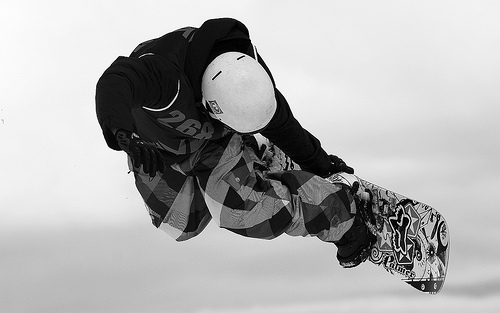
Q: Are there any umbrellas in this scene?
A: No, there are no umbrellas.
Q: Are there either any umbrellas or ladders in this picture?
A: No, there are no umbrellas or ladders.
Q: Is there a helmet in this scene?
A: Yes, there is a helmet.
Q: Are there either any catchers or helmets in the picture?
A: Yes, there is a helmet.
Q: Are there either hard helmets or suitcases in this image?
A: Yes, there is a hard helmet.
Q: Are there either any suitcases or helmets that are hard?
A: Yes, the helmet is hard.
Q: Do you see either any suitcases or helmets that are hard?
A: Yes, the helmet is hard.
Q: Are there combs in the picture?
A: No, there are no combs.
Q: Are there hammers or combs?
A: No, there are no combs or hammers.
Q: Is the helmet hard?
A: Yes, the helmet is hard.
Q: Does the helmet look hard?
A: Yes, the helmet is hard.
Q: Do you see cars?
A: No, there are no cars.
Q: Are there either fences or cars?
A: No, there are no cars or fences.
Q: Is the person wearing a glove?
A: Yes, the person is wearing a glove.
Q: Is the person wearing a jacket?
A: No, the person is wearing a glove.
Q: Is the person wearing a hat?
A: No, the person is wearing a glove.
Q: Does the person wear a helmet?
A: Yes, the person wears a helmet.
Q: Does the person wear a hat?
A: No, the person wears a helmet.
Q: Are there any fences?
A: No, there are no fences.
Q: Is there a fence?
A: No, there are no fences.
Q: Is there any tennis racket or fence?
A: No, there are no fences or rackets.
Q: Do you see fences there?
A: No, there are no fences.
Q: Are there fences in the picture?
A: No, there are no fences.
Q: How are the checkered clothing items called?
A: The clothing items are pants.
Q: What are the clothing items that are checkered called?
A: The clothing items are pants.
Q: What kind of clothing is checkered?
A: The clothing is pants.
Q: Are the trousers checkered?
A: Yes, the trousers are checkered.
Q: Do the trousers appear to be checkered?
A: Yes, the trousers are checkered.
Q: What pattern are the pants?
A: The pants are checkered.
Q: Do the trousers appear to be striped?
A: No, the trousers are checkered.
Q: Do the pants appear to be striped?
A: No, the pants are checkered.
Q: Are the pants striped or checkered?
A: The pants are checkered.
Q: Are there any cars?
A: No, there are no cars.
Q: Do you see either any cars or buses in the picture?
A: No, there are no cars or buses.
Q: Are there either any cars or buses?
A: No, there are no cars or buses.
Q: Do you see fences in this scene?
A: No, there are no fences.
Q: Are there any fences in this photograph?
A: No, there are no fences.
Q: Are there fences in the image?
A: No, there are no fences.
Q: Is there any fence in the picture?
A: No, there are no fences.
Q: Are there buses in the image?
A: No, there are no buses.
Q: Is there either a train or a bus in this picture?
A: No, there are no buses or trains.